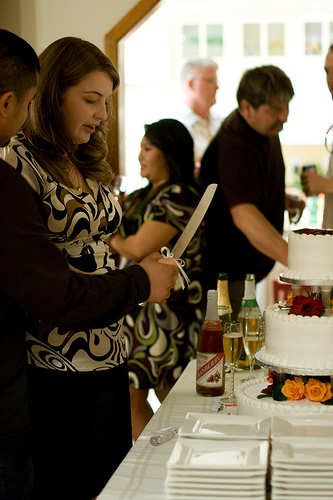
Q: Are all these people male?
A: No, they are both male and female.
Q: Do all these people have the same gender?
A: No, they are both male and female.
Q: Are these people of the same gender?
A: No, they are both male and female.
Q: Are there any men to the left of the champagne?
A: Yes, there is a man to the left of the champagne.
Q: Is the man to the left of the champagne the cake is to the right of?
A: Yes, the man is to the left of the champagne.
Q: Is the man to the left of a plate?
A: Yes, the man is to the left of a plate.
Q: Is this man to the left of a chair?
A: No, the man is to the left of a plate.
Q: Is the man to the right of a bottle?
A: No, the man is to the left of a bottle.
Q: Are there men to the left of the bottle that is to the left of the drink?
A: Yes, there is a man to the left of the bottle.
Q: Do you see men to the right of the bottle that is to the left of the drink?
A: No, the man is to the left of the bottle.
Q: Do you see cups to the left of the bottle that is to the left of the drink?
A: No, there is a man to the left of the bottle.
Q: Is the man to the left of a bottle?
A: Yes, the man is to the left of a bottle.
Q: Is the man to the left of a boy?
A: No, the man is to the left of a bottle.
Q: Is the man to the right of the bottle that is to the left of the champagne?
A: No, the man is to the left of the bottle.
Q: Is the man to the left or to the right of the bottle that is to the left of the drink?
A: The man is to the left of the bottle.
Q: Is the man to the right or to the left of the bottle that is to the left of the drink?
A: The man is to the left of the bottle.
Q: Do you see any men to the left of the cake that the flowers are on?
A: Yes, there is a man to the left of the cake.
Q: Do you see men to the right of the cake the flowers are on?
A: No, the man is to the left of the cake.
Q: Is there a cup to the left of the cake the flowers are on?
A: No, there is a man to the left of the cake.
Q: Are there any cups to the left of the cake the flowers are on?
A: No, there is a man to the left of the cake.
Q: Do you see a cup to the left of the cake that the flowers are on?
A: No, there is a man to the left of the cake.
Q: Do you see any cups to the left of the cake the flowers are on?
A: No, there is a man to the left of the cake.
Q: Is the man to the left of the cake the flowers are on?
A: Yes, the man is to the left of the cake.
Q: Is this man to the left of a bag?
A: No, the man is to the left of the cake.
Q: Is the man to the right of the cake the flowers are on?
A: No, the man is to the left of the cake.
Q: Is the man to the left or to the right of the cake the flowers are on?
A: The man is to the left of the cake.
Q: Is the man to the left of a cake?
A: Yes, the man is to the left of a cake.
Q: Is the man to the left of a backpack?
A: No, the man is to the left of a cake.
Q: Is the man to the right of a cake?
A: No, the man is to the left of a cake.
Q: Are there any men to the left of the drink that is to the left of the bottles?
A: Yes, there is a man to the left of the drink.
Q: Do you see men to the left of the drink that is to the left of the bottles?
A: Yes, there is a man to the left of the drink.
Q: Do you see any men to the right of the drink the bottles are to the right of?
A: No, the man is to the left of the drink.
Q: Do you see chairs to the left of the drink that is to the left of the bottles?
A: No, there is a man to the left of the drink.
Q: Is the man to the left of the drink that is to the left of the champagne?
A: Yes, the man is to the left of the drink.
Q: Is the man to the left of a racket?
A: No, the man is to the left of the drink.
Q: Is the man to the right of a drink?
A: No, the man is to the left of a drink.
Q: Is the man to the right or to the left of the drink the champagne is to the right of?
A: The man is to the left of the drink.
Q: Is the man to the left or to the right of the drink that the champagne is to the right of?
A: The man is to the left of the drink.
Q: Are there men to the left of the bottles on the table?
A: Yes, there is a man to the left of the bottles.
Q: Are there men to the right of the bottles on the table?
A: No, the man is to the left of the bottles.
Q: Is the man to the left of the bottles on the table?
A: Yes, the man is to the left of the bottles.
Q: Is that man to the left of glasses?
A: No, the man is to the left of the bottles.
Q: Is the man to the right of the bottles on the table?
A: No, the man is to the left of the bottles.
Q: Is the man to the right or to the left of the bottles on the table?
A: The man is to the left of the bottles.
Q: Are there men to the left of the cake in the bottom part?
A: Yes, there is a man to the left of the cake.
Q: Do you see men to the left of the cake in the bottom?
A: Yes, there is a man to the left of the cake.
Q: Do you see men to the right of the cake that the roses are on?
A: No, the man is to the left of the cake.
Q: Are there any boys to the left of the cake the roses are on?
A: No, there is a man to the left of the cake.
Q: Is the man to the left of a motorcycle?
A: No, the man is to the left of a cake.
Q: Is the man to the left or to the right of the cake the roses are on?
A: The man is to the left of the cake.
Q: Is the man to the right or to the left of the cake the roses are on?
A: The man is to the left of the cake.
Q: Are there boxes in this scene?
A: No, there are no boxes.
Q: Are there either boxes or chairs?
A: No, there are no boxes or chairs.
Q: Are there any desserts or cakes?
A: Yes, there is a cake.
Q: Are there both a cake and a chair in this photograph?
A: No, there is a cake but no chairs.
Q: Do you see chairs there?
A: No, there are no chairs.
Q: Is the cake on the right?
A: Yes, the cake is on the right of the image.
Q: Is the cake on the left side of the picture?
A: No, the cake is on the right of the image.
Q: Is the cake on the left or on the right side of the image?
A: The cake is on the right of the image.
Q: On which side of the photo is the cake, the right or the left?
A: The cake is on the right of the image.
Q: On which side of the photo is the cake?
A: The cake is on the right of the image.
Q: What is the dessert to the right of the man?
A: The dessert is a cake.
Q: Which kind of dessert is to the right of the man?
A: The dessert is a cake.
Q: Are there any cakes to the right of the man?
A: Yes, there is a cake to the right of the man.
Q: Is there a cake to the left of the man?
A: No, the cake is to the right of the man.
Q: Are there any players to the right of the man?
A: No, there is a cake to the right of the man.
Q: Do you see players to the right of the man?
A: No, there is a cake to the right of the man.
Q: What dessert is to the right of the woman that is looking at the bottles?
A: The dessert is a cake.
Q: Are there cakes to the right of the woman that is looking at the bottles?
A: Yes, there is a cake to the right of the woman.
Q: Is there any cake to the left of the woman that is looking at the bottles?
A: No, the cake is to the right of the woman.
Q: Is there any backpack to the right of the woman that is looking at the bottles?
A: No, there is a cake to the right of the woman.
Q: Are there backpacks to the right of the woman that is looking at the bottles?
A: No, there is a cake to the right of the woman.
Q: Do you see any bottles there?
A: Yes, there is a bottle.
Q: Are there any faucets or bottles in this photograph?
A: Yes, there is a bottle.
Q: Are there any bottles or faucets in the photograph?
A: Yes, there is a bottle.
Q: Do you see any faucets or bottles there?
A: Yes, there is a bottle.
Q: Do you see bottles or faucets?
A: Yes, there is a bottle.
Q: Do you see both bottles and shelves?
A: No, there is a bottle but no shelves.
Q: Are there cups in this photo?
A: No, there are no cups.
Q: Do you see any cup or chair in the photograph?
A: No, there are no cups or chairs.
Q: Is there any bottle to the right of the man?
A: Yes, there is a bottle to the right of the man.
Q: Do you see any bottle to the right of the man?
A: Yes, there is a bottle to the right of the man.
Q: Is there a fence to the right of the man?
A: No, there is a bottle to the right of the man.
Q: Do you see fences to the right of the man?
A: No, there is a bottle to the right of the man.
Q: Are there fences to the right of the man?
A: No, there is a bottle to the right of the man.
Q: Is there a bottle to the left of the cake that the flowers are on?
A: Yes, there is a bottle to the left of the cake.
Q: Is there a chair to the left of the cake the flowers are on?
A: No, there is a bottle to the left of the cake.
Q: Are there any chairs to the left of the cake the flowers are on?
A: No, there is a bottle to the left of the cake.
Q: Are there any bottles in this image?
A: Yes, there is a bottle.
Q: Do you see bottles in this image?
A: Yes, there is a bottle.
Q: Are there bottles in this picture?
A: Yes, there is a bottle.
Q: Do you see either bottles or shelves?
A: Yes, there is a bottle.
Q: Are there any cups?
A: No, there are no cups.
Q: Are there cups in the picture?
A: No, there are no cups.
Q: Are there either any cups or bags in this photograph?
A: No, there are no cups or bags.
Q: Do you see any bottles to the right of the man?
A: Yes, there is a bottle to the right of the man.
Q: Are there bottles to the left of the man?
A: No, the bottle is to the right of the man.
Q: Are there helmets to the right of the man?
A: No, there is a bottle to the right of the man.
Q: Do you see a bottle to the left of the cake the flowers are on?
A: Yes, there is a bottle to the left of the cake.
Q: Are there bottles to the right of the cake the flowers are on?
A: No, the bottle is to the left of the cake.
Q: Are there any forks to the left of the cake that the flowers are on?
A: No, there is a bottle to the left of the cake.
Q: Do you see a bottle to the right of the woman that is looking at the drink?
A: Yes, there is a bottle to the right of the woman.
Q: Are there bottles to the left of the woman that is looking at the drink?
A: No, the bottle is to the right of the woman.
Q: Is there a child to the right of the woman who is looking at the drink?
A: No, there is a bottle to the right of the woman.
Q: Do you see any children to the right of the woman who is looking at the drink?
A: No, there is a bottle to the right of the woman.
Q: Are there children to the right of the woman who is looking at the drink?
A: No, there is a bottle to the right of the woman.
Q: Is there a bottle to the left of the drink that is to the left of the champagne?
A: Yes, there is a bottle to the left of the drink.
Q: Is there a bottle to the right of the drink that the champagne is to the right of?
A: No, the bottle is to the left of the drink.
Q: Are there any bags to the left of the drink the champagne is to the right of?
A: No, there is a bottle to the left of the drink.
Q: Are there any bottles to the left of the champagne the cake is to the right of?
A: Yes, there is a bottle to the left of the champagne.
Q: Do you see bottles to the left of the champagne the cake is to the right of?
A: Yes, there is a bottle to the left of the champagne.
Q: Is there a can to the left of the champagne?
A: No, there is a bottle to the left of the champagne.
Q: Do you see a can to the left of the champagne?
A: No, there is a bottle to the left of the champagne.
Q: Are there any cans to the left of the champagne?
A: No, there is a bottle to the left of the champagne.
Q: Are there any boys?
A: No, there are no boys.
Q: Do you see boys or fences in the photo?
A: No, there are no boys or fences.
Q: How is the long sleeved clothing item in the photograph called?
A: The clothing item is a shirt.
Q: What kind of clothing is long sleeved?
A: The clothing is a shirt.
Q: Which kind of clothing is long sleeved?
A: The clothing is a shirt.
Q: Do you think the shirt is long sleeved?
A: Yes, the shirt is long sleeved.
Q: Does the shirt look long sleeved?
A: Yes, the shirt is long sleeved.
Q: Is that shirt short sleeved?
A: No, the shirt is long sleeved.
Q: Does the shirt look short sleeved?
A: No, the shirt is long sleeved.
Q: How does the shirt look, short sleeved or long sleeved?
A: The shirt is long sleeved.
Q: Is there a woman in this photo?
A: Yes, there is a woman.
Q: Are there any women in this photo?
A: Yes, there is a woman.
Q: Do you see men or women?
A: Yes, there is a woman.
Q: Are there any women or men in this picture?
A: Yes, there is a woman.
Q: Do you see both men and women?
A: Yes, there are both a woman and a man.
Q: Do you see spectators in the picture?
A: No, there are no spectators.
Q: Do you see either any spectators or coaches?
A: No, there are no spectators or coaches.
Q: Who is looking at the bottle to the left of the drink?
A: The woman is looking at the bottle.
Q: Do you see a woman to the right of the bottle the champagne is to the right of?
A: No, the woman is to the left of the bottle.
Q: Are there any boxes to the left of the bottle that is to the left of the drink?
A: No, there is a woman to the left of the bottle.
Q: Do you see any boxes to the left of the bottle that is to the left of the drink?
A: No, there is a woman to the left of the bottle.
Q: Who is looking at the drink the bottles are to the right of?
A: The woman is looking at the drink.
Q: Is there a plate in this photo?
A: Yes, there is a plate.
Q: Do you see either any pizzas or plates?
A: Yes, there is a plate.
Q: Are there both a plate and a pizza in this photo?
A: No, there is a plate but no pizzas.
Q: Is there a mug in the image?
A: No, there are no mugs.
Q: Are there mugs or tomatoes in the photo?
A: No, there are no mugs or tomatoes.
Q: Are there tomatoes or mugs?
A: No, there are no mugs or tomatoes.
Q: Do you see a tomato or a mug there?
A: No, there are no mugs or tomatoes.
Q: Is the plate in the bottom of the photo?
A: Yes, the plate is in the bottom of the image.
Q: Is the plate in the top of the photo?
A: No, the plate is in the bottom of the image.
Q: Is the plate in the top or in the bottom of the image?
A: The plate is in the bottom of the image.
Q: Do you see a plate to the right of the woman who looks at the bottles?
A: Yes, there is a plate to the right of the woman.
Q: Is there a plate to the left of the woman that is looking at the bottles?
A: No, the plate is to the right of the woman.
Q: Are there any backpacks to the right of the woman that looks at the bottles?
A: No, there is a plate to the right of the woman.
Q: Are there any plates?
A: Yes, there is a plate.